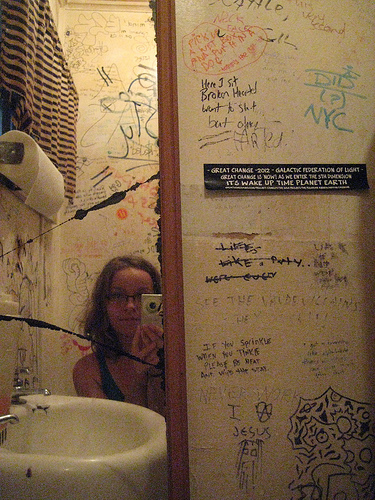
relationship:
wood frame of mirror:
[146, 2, 188, 492] [2, 4, 172, 497]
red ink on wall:
[184, 21, 263, 78] [171, 0, 375, 499]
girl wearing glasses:
[73, 252, 173, 421] [104, 284, 156, 310]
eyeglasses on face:
[102, 289, 144, 304] [54, 237, 184, 345]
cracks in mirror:
[1, 165, 157, 364] [0, 1, 167, 446]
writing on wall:
[227, 401, 273, 495] [175, 0, 374, 498]